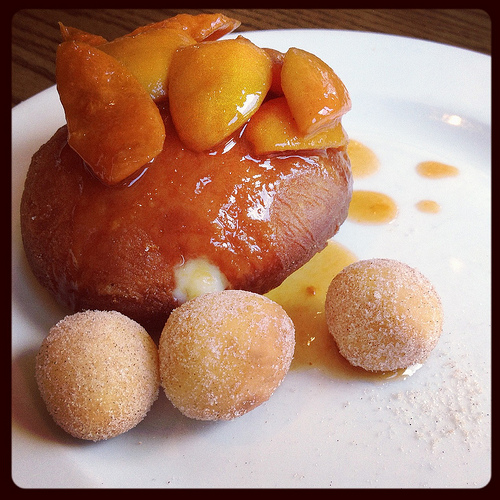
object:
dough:
[324, 257, 442, 374]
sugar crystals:
[329, 364, 492, 489]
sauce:
[344, 134, 463, 229]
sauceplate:
[345, 74, 494, 427]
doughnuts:
[32, 309, 161, 444]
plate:
[12, 27, 493, 489]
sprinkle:
[371, 363, 492, 465]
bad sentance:
[346, 115, 460, 228]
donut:
[24, 95, 351, 321]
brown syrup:
[77, 100, 321, 269]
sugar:
[388, 371, 490, 456]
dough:
[158, 287, 295, 421]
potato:
[22, 116, 356, 329]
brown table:
[10, 7, 492, 111]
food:
[20, 14, 445, 444]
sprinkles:
[111, 352, 138, 395]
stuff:
[172, 255, 227, 306]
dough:
[19, 89, 352, 323]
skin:
[277, 196, 327, 243]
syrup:
[306, 285, 317, 299]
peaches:
[52, 13, 354, 187]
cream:
[172, 257, 230, 304]